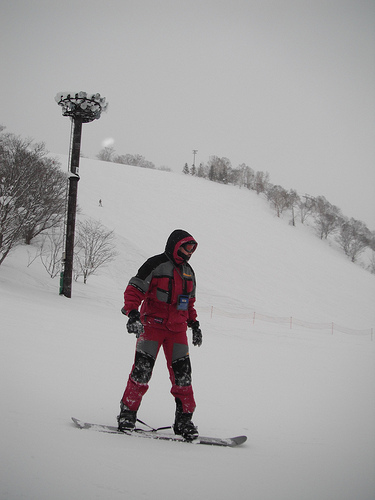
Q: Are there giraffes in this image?
A: No, there are no giraffes.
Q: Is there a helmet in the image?
A: No, there are no helmets.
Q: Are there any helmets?
A: No, there are no helmets.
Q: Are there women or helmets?
A: No, there are no helmets or women.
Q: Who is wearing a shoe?
A: The man is wearing a shoe.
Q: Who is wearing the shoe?
A: The man is wearing a shoe.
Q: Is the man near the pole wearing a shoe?
A: Yes, the man is wearing a shoe.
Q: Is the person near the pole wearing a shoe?
A: Yes, the man is wearing a shoe.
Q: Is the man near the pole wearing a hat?
A: No, the man is wearing a shoe.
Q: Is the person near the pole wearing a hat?
A: No, the man is wearing a shoe.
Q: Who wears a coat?
A: The man wears a coat.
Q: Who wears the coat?
A: The man wears a coat.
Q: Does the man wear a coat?
A: Yes, the man wears a coat.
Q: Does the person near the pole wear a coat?
A: Yes, the man wears a coat.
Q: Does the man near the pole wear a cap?
A: No, the man wears a coat.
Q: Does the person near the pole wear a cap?
A: No, the man wears a coat.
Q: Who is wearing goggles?
A: The man is wearing goggles.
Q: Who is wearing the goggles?
A: The man is wearing goggles.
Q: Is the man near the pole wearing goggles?
A: Yes, the man is wearing goggles.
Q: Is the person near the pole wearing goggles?
A: Yes, the man is wearing goggles.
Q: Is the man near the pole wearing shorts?
A: No, the man is wearing goggles.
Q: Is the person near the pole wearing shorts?
A: No, the man is wearing goggles.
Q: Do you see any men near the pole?
A: Yes, there is a man near the pole.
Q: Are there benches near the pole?
A: No, there is a man near the pole.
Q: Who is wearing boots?
A: The man is wearing boots.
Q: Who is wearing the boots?
A: The man is wearing boots.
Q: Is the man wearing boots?
A: Yes, the man is wearing boots.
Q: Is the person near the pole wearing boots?
A: Yes, the man is wearing boots.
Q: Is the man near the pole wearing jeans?
A: No, the man is wearing boots.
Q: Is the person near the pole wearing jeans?
A: No, the man is wearing boots.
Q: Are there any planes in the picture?
A: No, there are no planes.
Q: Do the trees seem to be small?
A: Yes, the trees are small.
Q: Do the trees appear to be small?
A: Yes, the trees are small.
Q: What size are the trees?
A: The trees are small.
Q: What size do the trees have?
A: The trees have small size.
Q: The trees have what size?
A: The trees are small.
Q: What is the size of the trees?
A: The trees are small.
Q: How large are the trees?
A: The trees are small.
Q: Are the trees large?
A: No, the trees are small.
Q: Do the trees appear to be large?
A: No, the trees are small.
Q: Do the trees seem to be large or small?
A: The trees are small.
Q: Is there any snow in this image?
A: Yes, there is snow.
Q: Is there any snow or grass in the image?
A: Yes, there is snow.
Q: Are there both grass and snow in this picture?
A: No, there is snow but no grass.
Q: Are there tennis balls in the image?
A: No, there are no tennis balls.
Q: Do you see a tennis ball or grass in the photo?
A: No, there are no tennis balls or grass.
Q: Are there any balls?
A: No, there are no balls.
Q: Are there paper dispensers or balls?
A: No, there are no balls or paper dispensers.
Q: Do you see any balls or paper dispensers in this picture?
A: No, there are no balls or paper dispensers.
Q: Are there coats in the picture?
A: Yes, there is a coat.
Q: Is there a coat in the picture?
A: Yes, there is a coat.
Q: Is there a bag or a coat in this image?
A: Yes, there is a coat.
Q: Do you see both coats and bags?
A: No, there is a coat but no bags.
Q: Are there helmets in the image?
A: No, there are no helmets.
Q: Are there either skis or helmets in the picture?
A: No, there are no helmets or skis.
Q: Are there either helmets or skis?
A: No, there are no helmets or skis.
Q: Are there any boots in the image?
A: Yes, there are boots.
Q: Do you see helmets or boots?
A: Yes, there are boots.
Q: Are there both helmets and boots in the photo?
A: No, there are boots but no helmets.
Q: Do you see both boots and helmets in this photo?
A: No, there are boots but no helmets.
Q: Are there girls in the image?
A: No, there are no girls.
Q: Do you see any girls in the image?
A: No, there are no girls.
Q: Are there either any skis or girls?
A: No, there are no girls or skis.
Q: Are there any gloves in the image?
A: Yes, there are gloves.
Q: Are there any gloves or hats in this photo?
A: Yes, there are gloves.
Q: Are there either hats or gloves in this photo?
A: Yes, there are gloves.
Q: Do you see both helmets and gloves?
A: No, there are gloves but no helmets.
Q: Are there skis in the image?
A: No, there are no skis.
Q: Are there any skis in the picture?
A: No, there are no skis.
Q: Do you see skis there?
A: No, there are no skis.